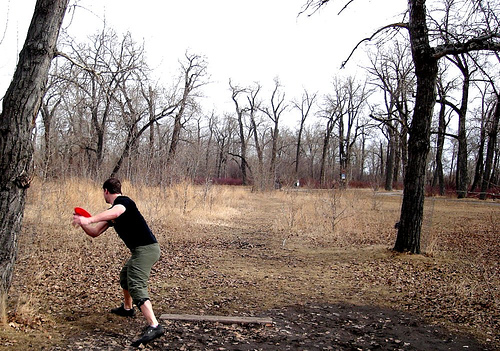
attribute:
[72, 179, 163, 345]
man — preparing to throw, standing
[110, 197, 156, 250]
shirt — black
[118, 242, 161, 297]
shorts — green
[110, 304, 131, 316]
shoe — black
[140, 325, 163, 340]
shoe — black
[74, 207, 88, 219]
frisbee — red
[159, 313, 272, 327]
plywood — brown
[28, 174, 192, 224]
grass — tall, dry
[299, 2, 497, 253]
tree — leafless, tall, bare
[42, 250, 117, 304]
leaves — brown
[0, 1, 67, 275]
tree trunk — large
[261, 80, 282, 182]
tree — leafless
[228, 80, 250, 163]
tree — leafless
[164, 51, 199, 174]
tree — leafless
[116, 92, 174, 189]
tree — leafless